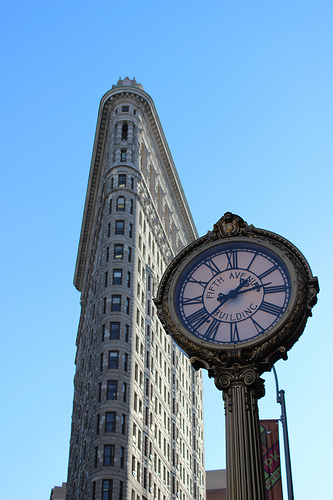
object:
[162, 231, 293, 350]
clock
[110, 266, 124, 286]
window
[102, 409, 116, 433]
window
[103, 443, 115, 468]
window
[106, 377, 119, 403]
window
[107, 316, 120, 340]
window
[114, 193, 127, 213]
window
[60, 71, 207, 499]
building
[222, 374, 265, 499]
pole